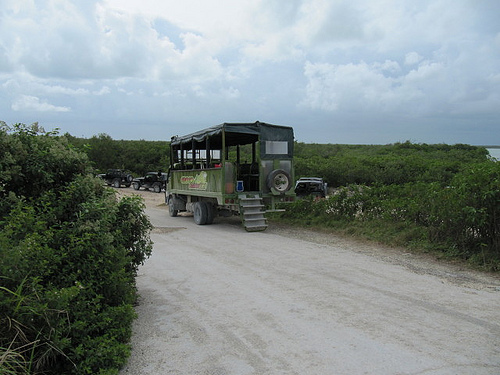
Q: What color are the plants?
A: Green.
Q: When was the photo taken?
A: Daytime.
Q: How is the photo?
A: Clear.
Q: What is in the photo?
A: A vehicle.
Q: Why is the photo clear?
A: Its during the day.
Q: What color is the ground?
A: White.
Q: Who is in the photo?
A: Nobody.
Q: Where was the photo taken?
A: Roadside beside bushes.